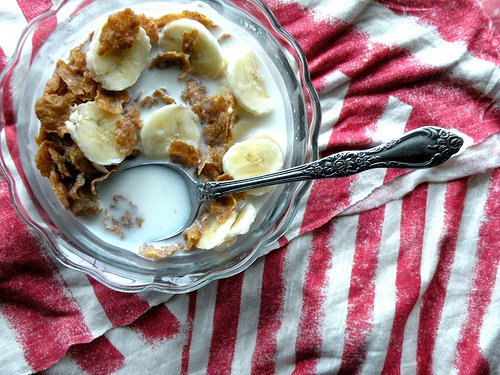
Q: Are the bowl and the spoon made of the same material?
A: No, the bowl is made of glass and the spoon is made of metal.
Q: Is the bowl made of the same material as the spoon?
A: No, the bowl is made of glass and the spoon is made of metal.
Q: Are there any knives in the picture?
A: No, there are no knives.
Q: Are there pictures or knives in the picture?
A: No, there are no knives or pictures.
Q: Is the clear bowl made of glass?
A: Yes, the bowl is made of glass.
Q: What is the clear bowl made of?
A: The bowl is made of glass.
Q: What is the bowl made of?
A: The bowl is made of glass.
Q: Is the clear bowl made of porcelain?
A: No, the bowl is made of glass.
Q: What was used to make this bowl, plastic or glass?
A: The bowl is made of glass.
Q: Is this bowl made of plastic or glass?
A: The bowl is made of glass.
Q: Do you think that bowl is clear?
A: Yes, the bowl is clear.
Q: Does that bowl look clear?
A: Yes, the bowl is clear.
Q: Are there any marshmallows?
A: No, there are no marshmallows.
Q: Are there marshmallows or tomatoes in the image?
A: No, there are no marshmallows or tomatoes.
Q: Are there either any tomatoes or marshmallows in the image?
A: No, there are no marshmallows or tomatoes.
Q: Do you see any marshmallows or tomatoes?
A: No, there are no marshmallows or tomatoes.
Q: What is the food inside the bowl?
A: The food is cereal.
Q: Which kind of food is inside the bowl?
A: The food is cereal.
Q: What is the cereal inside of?
A: The cereal is inside the bowl.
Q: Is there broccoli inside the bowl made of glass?
A: No, there is cereal inside the bowl.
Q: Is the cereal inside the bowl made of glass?
A: Yes, the cereal is inside the bowl.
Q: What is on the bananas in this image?
A: The cereal is on the bananas.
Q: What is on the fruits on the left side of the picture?
A: The cereal is on the bananas.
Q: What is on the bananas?
A: The cereal is on the bananas.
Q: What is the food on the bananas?
A: The food is cereal.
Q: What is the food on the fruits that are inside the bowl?
A: The food is cereal.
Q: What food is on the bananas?
A: The food is cereal.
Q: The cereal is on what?
A: The cereal is on the bananas.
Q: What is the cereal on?
A: The cereal is on the bananas.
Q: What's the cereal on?
A: The cereal is on the bananas.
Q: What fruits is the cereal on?
A: The cereal is on the bananas.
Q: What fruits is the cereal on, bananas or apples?
A: The cereal is on bananas.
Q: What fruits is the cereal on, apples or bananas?
A: The cereal is on bananas.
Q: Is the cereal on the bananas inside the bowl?
A: Yes, the cereal is on the bananas.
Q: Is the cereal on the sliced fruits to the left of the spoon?
A: Yes, the cereal is on the bananas.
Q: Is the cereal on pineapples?
A: No, the cereal is on the bananas.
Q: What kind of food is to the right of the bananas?
A: The food is cereal.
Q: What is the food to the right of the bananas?
A: The food is cereal.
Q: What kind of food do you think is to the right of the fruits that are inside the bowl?
A: The food is cereal.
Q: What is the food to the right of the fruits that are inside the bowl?
A: The food is cereal.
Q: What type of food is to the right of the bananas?
A: The food is cereal.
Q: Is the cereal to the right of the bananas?
A: Yes, the cereal is to the right of the bananas.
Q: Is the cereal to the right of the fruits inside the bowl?
A: Yes, the cereal is to the right of the bananas.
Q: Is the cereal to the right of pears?
A: No, the cereal is to the right of the bananas.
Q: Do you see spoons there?
A: Yes, there is a spoon.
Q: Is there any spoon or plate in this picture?
A: Yes, there is a spoon.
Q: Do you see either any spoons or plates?
A: Yes, there is a spoon.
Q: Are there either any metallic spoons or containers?
A: Yes, there is a metal spoon.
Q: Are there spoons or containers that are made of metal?
A: Yes, the spoon is made of metal.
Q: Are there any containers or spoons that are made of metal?
A: Yes, the spoon is made of metal.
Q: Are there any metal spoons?
A: Yes, there is a metal spoon.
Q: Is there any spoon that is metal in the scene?
A: Yes, there is a metal spoon.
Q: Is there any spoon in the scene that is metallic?
A: Yes, there is a spoon that is metallic.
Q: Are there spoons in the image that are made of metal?
A: Yes, there is a spoon that is made of metal.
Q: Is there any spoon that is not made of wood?
A: Yes, there is a spoon that is made of metal.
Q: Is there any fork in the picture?
A: No, there are no forks.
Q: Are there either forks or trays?
A: No, there are no forks or trays.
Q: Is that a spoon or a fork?
A: That is a spoon.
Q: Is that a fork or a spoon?
A: That is a spoon.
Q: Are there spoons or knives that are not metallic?
A: No, there is a spoon but it is metallic.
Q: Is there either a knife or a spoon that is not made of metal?
A: No, there is a spoon but it is made of metal.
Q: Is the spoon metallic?
A: Yes, the spoon is metallic.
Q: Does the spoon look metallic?
A: Yes, the spoon is metallic.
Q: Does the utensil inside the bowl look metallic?
A: Yes, the spoon is metallic.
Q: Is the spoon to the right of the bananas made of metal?
A: Yes, the spoon is made of metal.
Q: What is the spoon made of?
A: The spoon is made of metal.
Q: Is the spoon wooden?
A: No, the spoon is metallic.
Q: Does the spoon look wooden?
A: No, the spoon is metallic.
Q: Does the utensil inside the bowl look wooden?
A: No, the spoon is metallic.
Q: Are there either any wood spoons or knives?
A: No, there is a spoon but it is metallic.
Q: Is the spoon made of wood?
A: No, the spoon is made of metal.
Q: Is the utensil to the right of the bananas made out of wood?
A: No, the spoon is made of metal.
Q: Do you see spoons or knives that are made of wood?
A: No, there is a spoon but it is made of metal.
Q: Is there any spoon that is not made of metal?
A: No, there is a spoon but it is made of metal.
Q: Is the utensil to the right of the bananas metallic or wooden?
A: The spoon is metallic.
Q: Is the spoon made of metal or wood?
A: The spoon is made of metal.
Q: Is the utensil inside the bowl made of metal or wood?
A: The spoon is made of metal.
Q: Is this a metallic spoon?
A: Yes, this is a metallic spoon.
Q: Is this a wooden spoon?
A: No, this is a metallic spoon.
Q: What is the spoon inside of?
A: The spoon is inside the bowl.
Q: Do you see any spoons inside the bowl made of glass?
A: Yes, there is a spoon inside the bowl.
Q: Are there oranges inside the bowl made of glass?
A: No, there is a spoon inside the bowl.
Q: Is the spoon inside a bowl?
A: Yes, the spoon is inside a bowl.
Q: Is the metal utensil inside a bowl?
A: Yes, the spoon is inside a bowl.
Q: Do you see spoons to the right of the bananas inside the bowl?
A: Yes, there is a spoon to the right of the bananas.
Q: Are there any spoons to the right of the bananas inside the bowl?
A: Yes, there is a spoon to the right of the bananas.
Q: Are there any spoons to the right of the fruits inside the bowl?
A: Yes, there is a spoon to the right of the bananas.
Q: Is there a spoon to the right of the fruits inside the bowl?
A: Yes, there is a spoon to the right of the bananas.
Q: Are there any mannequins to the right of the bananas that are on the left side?
A: No, there is a spoon to the right of the bananas.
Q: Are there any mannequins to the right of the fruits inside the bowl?
A: No, there is a spoon to the right of the bananas.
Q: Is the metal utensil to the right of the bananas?
A: Yes, the spoon is to the right of the bananas.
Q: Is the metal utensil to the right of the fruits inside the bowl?
A: Yes, the spoon is to the right of the bananas.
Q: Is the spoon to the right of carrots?
A: No, the spoon is to the right of the bananas.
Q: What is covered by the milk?
A: The spoon is covered by the milk.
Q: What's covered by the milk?
A: The spoon is covered by the milk.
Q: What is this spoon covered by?
A: The spoon is covered by the milk.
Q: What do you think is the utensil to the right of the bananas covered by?
A: The spoon is covered by the milk.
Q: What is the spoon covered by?
A: The spoon is covered by the milk.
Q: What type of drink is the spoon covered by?
A: The spoon is covered by the milk.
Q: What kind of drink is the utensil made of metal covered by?
A: The spoon is covered by the milk.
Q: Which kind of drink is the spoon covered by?
A: The spoon is covered by the milk.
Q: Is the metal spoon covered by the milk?
A: Yes, the spoon is covered by the milk.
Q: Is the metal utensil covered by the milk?
A: Yes, the spoon is covered by the milk.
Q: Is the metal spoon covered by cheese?
A: No, the spoon is covered by the milk.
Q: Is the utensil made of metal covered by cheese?
A: No, the spoon is covered by the milk.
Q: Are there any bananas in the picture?
A: Yes, there are bananas.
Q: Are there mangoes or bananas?
A: Yes, there are bananas.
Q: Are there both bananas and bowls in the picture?
A: Yes, there are both bananas and a bowl.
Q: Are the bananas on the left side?
A: Yes, the bananas are on the left of the image.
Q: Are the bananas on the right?
A: No, the bananas are on the left of the image.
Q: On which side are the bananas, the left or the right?
A: The bananas are on the left of the image.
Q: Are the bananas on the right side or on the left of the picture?
A: The bananas are on the left of the image.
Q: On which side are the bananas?
A: The bananas are on the left of the image.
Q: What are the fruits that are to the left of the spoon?
A: The fruits are bananas.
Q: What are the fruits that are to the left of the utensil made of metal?
A: The fruits are bananas.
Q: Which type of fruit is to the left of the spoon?
A: The fruits are bananas.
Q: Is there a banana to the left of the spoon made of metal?
A: Yes, there are bananas to the left of the spoon.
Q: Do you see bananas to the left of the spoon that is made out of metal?
A: Yes, there are bananas to the left of the spoon.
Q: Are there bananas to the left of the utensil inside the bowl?
A: Yes, there are bananas to the left of the spoon.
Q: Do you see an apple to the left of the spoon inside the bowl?
A: No, there are bananas to the left of the spoon.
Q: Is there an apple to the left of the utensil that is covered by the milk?
A: No, there are bananas to the left of the spoon.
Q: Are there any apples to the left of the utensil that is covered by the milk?
A: No, there are bananas to the left of the spoon.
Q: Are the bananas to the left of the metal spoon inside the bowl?
A: Yes, the bananas are to the left of the spoon.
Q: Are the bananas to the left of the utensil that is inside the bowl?
A: Yes, the bananas are to the left of the spoon.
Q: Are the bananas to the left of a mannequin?
A: No, the bananas are to the left of the spoon.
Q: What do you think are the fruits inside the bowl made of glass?
A: The fruits are bananas.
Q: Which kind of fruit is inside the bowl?
A: The fruits are bananas.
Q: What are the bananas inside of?
A: The bananas are inside the bowl.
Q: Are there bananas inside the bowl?
A: Yes, there are bananas inside the bowl.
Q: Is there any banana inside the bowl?
A: Yes, there are bananas inside the bowl.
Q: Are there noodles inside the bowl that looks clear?
A: No, there are bananas inside the bowl.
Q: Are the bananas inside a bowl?
A: Yes, the bananas are inside a bowl.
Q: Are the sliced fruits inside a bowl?
A: Yes, the bananas are inside a bowl.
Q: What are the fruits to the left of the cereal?
A: The fruits are bananas.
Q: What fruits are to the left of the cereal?
A: The fruits are bananas.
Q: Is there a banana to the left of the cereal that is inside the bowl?
A: Yes, there are bananas to the left of the cereal.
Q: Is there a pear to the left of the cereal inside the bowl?
A: No, there are bananas to the left of the cereal.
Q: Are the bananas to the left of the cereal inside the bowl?
A: Yes, the bananas are to the left of the cereal.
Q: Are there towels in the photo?
A: Yes, there is a towel.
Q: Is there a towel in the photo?
A: Yes, there is a towel.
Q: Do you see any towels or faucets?
A: Yes, there is a towel.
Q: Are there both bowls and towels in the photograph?
A: Yes, there are both a towel and a bowl.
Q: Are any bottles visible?
A: No, there are no bottles.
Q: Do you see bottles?
A: No, there are no bottles.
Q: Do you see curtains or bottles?
A: No, there are no bottles or curtains.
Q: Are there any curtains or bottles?
A: No, there are no bottles or curtains.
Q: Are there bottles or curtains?
A: No, there are no bottles or curtains.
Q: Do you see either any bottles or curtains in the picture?
A: No, there are no bottles or curtains.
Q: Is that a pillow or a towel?
A: That is a towel.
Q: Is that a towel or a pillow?
A: That is a towel.